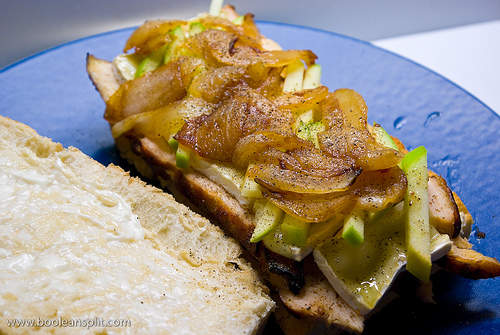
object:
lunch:
[0, 0, 500, 335]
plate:
[0, 14, 500, 335]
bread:
[0, 0, 500, 334]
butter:
[89, 184, 129, 213]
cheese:
[346, 261, 353, 271]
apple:
[400, 145, 433, 285]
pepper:
[426, 175, 458, 239]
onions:
[216, 76, 239, 92]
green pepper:
[137, 59, 156, 76]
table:
[0, 0, 500, 120]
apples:
[342, 224, 355, 233]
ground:
[0, 0, 500, 116]